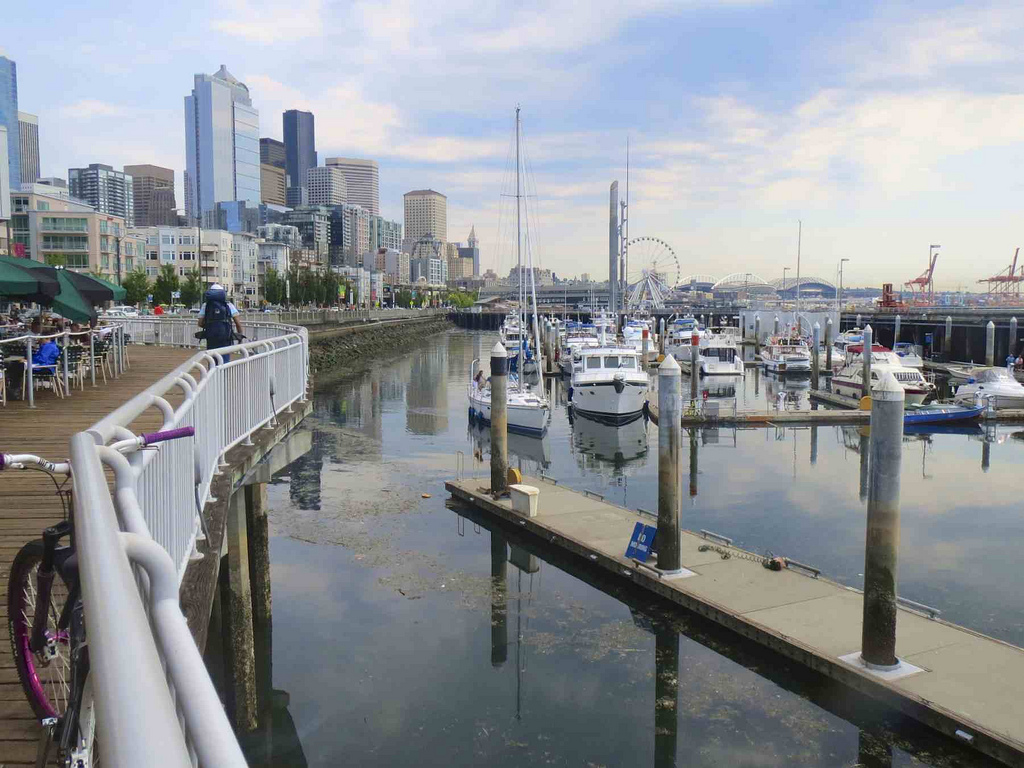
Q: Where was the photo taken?
A: It was taken at the marina.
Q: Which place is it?
A: It is a marina.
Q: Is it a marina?
A: Yes, it is a marina.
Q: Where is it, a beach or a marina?
A: It is a marina.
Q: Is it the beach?
A: No, it is the marina.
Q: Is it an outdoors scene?
A: Yes, it is outdoors.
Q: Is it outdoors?
A: Yes, it is outdoors.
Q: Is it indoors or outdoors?
A: It is outdoors.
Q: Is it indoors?
A: No, it is outdoors.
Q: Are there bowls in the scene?
A: No, there are no bowls.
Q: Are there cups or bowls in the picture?
A: No, there are no bowls or cups.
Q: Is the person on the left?
A: Yes, the person is on the left of the image.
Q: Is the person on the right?
A: No, the person is on the left of the image.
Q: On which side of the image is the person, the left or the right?
A: The person is on the left of the image.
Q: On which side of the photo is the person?
A: The person is on the left of the image.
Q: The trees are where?
A: The trees are on the street.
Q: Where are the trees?
A: The trees are on the street.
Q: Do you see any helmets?
A: No, there are no helmets.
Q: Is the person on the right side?
A: No, the person is on the left of the image.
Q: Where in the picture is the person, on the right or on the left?
A: The person is on the left of the image.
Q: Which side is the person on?
A: The person is on the left of the image.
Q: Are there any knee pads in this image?
A: No, there are no knee pads.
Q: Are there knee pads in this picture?
A: No, there are no knee pads.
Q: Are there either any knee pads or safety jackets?
A: No, there are no knee pads or safety jackets.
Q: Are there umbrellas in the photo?
A: Yes, there is an umbrella.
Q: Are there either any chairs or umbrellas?
A: Yes, there is an umbrella.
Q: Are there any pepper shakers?
A: No, there are no pepper shakers.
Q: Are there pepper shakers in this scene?
A: No, there are no pepper shakers.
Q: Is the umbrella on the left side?
A: Yes, the umbrella is on the left of the image.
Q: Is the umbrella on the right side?
A: No, the umbrella is on the left of the image.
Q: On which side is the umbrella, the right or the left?
A: The umbrella is on the left of the image.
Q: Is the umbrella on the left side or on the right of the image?
A: The umbrella is on the left of the image.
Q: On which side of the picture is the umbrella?
A: The umbrella is on the left of the image.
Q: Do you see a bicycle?
A: Yes, there is a bicycle.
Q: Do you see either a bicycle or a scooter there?
A: Yes, there is a bicycle.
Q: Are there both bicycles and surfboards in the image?
A: No, there is a bicycle but no surfboards.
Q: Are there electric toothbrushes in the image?
A: No, there are no electric toothbrushes.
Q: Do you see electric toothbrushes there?
A: No, there are no electric toothbrushes.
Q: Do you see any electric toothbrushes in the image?
A: No, there are no electric toothbrushes.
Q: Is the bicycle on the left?
A: Yes, the bicycle is on the left of the image.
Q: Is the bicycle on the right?
A: No, the bicycle is on the left of the image.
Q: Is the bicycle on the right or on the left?
A: The bicycle is on the left of the image.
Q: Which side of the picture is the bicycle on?
A: The bicycle is on the left of the image.